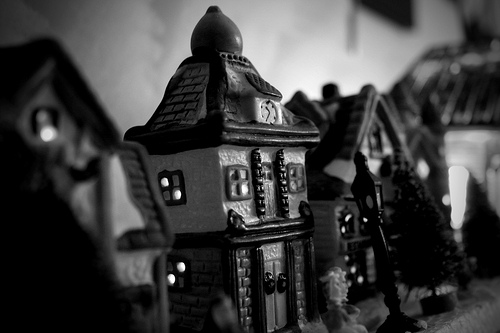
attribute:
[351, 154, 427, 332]
lamp post — toy, black, small, here, street light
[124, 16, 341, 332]
house — toy, two toned, brick, figurine, tall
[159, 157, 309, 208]
windows — small, closed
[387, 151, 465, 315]
tree — pine, here, slanting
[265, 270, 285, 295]
handles — black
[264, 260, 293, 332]
door — two sided, small, closed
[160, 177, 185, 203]
light — shining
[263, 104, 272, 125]
clock hands — black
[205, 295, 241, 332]
doll — small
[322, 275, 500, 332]
ground — here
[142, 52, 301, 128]
roof — here